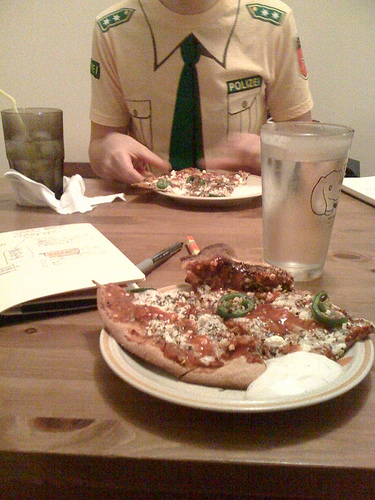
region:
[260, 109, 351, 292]
A clear glass of water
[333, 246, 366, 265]
A small knot in the table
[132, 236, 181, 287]
A grey and black pen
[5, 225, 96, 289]
Math homework in a small notebook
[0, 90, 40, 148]
A yellow straw in the glass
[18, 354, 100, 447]
An unpolished wooden table beneath the plates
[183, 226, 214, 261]
An orange pen on the table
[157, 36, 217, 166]
A green tie on the man's shirt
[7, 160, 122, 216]
White napkins near the cup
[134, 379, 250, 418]
Gold trim around the white plate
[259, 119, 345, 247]
this is a glass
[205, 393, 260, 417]
this is a plate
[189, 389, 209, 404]
the plate is white in color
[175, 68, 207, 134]
this is a neck tie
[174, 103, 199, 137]
the tie is green in color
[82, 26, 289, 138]
this is a man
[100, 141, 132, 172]
the man is light skinned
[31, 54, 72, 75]
this is a wall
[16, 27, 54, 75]
the wall is white in color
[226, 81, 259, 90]
this is a writing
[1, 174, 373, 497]
a thick wooden table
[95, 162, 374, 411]
two plates on either side of table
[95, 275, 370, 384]
large piece of pizza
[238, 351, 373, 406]
white sauce near edge of plate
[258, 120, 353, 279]
plastic cup with clear liquid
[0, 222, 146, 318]
folded white paper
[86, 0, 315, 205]
person wearing a shirt caricaturing a police uniform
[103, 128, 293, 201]
person's hands near pizza on their plate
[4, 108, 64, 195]
a grey cup with ice and liquid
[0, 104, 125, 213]
cup resting on white napkin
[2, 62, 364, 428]
A man eating pizza at a table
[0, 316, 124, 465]
An unpolished wooden table beneath the plates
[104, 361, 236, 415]
A clean white plate beneath the pizza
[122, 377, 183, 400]
A gold trim around the white plate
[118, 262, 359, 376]
Multiple slices of pizza on the plate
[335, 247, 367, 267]
A small brown knot in the wooden table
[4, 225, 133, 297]
Math homework in the notebook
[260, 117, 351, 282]
A clear glass of water on the table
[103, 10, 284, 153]
person wears tan shirt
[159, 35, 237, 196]
green tie drawn on shirt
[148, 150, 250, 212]
person is eating pizza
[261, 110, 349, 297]
clear glass near pizza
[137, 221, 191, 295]
pen on table behind pizza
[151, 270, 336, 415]
pizza on white and gold plate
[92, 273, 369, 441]
plate is on brown table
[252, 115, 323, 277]
water is in clear glass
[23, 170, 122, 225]
white napkin is under glass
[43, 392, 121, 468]
dark brown knots in table